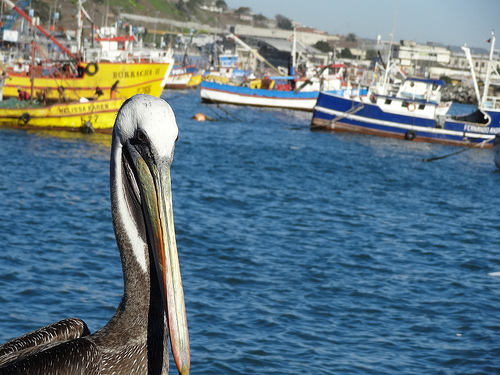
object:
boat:
[2, 94, 128, 136]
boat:
[197, 28, 370, 112]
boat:
[0, 20, 171, 108]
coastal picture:
[2, 0, 494, 370]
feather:
[60, 320, 77, 336]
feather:
[34, 358, 54, 372]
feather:
[15, 339, 30, 349]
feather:
[132, 344, 142, 356]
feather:
[97, 350, 116, 357]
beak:
[128, 142, 192, 375]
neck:
[109, 131, 169, 340]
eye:
[137, 130, 147, 142]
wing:
[1, 315, 88, 365]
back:
[1, 318, 103, 373]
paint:
[1, 109, 114, 130]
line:
[1, 76, 165, 90]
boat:
[308, 32, 497, 149]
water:
[0, 85, 498, 371]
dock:
[269, 47, 500, 131]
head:
[104, 94, 181, 170]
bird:
[3, 94, 192, 375]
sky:
[321, 0, 500, 51]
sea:
[11, 141, 100, 214]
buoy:
[188, 111, 218, 123]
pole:
[478, 30, 497, 112]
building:
[340, 35, 499, 92]